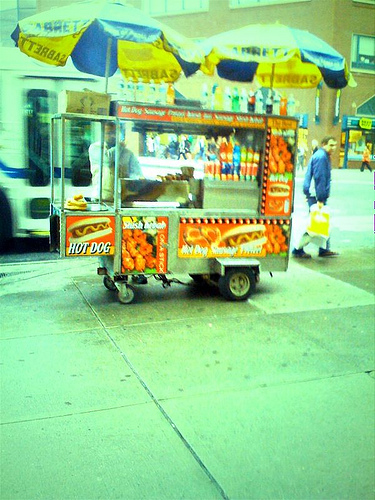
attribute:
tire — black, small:
[221, 267, 255, 300]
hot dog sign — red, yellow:
[65, 101, 299, 274]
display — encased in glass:
[52, 110, 264, 216]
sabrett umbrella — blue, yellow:
[10, 1, 205, 86]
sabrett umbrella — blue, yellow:
[198, 19, 357, 87]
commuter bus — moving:
[0, 45, 170, 244]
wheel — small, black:
[116, 283, 137, 304]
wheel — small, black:
[102, 275, 116, 289]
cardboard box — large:
[56, 90, 109, 116]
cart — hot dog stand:
[47, 99, 301, 304]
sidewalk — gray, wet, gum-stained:
[0, 245, 374, 499]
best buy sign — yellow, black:
[359, 117, 372, 129]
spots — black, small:
[21, 283, 369, 410]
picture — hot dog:
[65, 126, 295, 277]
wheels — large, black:
[186, 264, 255, 299]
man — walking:
[293, 138, 340, 261]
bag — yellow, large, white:
[304, 203, 331, 244]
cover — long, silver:
[214, 258, 262, 276]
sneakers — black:
[292, 245, 340, 258]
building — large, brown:
[2, 0, 374, 171]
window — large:
[344, 128, 374, 164]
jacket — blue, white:
[302, 149, 331, 199]